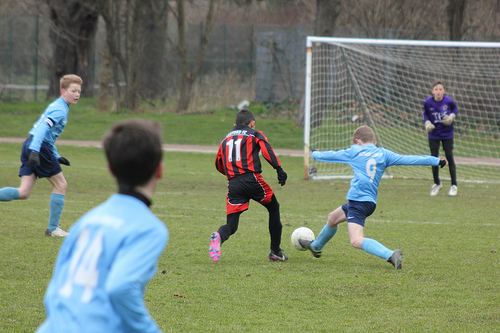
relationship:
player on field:
[1, 61, 78, 246] [164, 265, 498, 327]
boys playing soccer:
[0, 60, 485, 330] [1, 53, 487, 330]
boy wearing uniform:
[1, 70, 81, 242] [311, 141, 439, 225]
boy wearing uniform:
[298, 125, 446, 269] [311, 141, 439, 225]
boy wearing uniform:
[35, 123, 168, 331] [311, 141, 439, 225]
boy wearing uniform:
[202, 105, 292, 267] [311, 141, 439, 225]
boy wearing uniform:
[416, 78, 462, 198] [311, 141, 439, 225]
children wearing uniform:
[2, 72, 463, 331] [304, 140, 451, 231]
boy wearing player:
[306, 127, 446, 275] [298, 125, 447, 269]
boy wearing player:
[1, 70, 81, 242] [298, 125, 447, 269]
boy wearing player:
[35, 123, 168, 331] [298, 125, 447, 269]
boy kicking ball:
[298, 125, 446, 269] [292, 225, 319, 248]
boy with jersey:
[422, 80, 458, 196] [421, 97, 459, 129]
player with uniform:
[210, 110, 291, 262] [216, 126, 281, 204]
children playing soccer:
[0, 74, 460, 333] [269, 178, 389, 285]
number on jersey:
[223, 135, 244, 165] [313, 142, 439, 204]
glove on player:
[25, 148, 47, 170] [190, 68, 339, 285]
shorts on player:
[222, 173, 274, 215] [318, 111, 485, 330]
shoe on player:
[448, 187, 463, 199] [203, 93, 315, 299]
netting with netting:
[302, 36, 499, 186] [302, 36, 499, 186]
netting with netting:
[302, 36, 499, 186] [301, 19, 478, 200]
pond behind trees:
[6, 76, 108, 103] [165, 6, 297, 98]